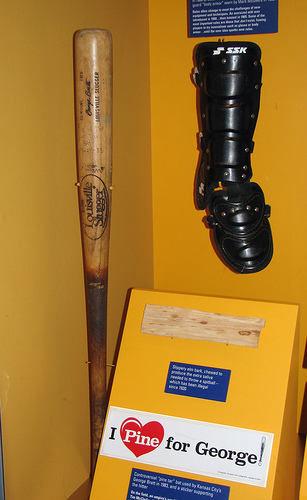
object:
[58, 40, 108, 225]
bat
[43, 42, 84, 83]
piece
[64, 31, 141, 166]
pine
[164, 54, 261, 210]
brace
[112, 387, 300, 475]
sticker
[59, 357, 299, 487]
bumper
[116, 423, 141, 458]
letter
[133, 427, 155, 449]
n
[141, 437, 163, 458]
e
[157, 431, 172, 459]
f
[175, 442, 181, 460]
o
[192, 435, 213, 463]
g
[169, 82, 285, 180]
shin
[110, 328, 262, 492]
display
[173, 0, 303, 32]
sign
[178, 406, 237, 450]
background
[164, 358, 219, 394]
lettering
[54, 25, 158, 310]
specimen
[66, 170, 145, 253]
slugger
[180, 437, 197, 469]
r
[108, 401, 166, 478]
heart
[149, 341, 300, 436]
label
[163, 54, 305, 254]
padding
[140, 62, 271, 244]
wall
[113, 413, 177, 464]
pine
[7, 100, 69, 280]
wall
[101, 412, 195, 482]
shape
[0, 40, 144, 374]
wood